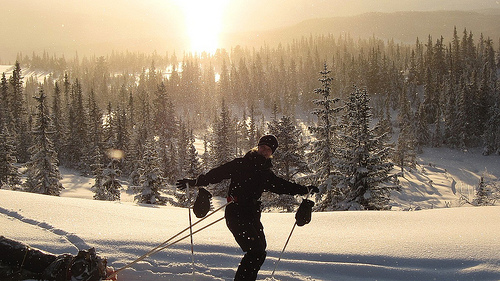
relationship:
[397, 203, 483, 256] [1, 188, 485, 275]
snow covering ground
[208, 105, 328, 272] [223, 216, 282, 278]
woman wears pants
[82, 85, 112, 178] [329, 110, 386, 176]
tree covered by snow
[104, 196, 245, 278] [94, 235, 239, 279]
pole in snow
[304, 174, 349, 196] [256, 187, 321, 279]
ski hand around ski pole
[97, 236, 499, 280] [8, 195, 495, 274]
shadow on snow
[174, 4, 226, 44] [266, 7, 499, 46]
sun shines over mountains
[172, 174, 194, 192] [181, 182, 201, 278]
hand holding ski pole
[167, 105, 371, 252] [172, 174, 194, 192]
person has hand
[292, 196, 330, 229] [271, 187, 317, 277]
glove hanging from ski pole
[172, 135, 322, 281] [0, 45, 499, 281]
person standing on snow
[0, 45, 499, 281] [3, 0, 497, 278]
snow covering mountain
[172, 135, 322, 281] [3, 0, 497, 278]
person standing on mountain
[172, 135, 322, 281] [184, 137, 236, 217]
person has bags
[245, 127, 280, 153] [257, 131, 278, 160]
skier's hat on head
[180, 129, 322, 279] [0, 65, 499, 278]
man skating on snow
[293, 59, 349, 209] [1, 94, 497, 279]
tree covered by snow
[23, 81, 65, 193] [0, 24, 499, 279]
tree covered by snow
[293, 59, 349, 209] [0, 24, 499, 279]
tree covered by snow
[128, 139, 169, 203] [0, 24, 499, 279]
tree covered by snow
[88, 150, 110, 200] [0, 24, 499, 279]
tree covered by snow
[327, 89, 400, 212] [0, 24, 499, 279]
tree covered by snow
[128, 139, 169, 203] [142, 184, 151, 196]
tree covered by snow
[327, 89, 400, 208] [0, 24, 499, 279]
tree covered by snow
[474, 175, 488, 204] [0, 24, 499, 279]
tree covered by snow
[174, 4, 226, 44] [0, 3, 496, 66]
sun in sky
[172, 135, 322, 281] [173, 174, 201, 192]
person wearing gloves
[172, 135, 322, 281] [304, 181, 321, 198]
person wearing gloves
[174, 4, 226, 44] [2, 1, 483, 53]
sun in sky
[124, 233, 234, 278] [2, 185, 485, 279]
tracks in snow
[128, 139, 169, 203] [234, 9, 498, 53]
tree are on mountain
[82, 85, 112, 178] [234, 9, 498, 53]
tree are on mountain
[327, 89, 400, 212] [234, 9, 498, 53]
tree are on mountain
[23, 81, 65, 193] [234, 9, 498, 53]
tree are on mountain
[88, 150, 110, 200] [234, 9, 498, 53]
tree are on mountain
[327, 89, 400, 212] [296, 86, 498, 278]
tree covered with snow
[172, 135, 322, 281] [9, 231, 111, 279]
person holding sled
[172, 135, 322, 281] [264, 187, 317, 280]
person holding ski pole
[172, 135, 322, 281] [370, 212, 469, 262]
person standing on snow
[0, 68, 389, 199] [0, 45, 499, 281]
trees with snow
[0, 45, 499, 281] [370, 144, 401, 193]
snow on branches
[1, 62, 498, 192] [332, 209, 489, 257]
trees are in snow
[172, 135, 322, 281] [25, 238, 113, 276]
person pulling a sled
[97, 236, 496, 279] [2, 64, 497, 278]
shadow on ground